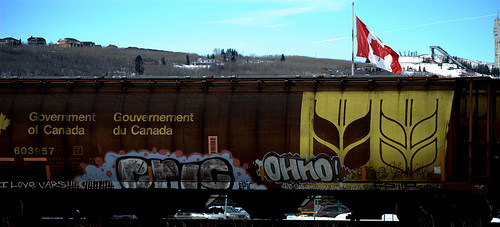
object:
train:
[0, 75, 499, 227]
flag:
[355, 16, 402, 75]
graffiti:
[254, 151, 349, 185]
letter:
[113, 112, 122, 123]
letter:
[130, 125, 139, 136]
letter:
[91, 112, 97, 123]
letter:
[166, 127, 174, 136]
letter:
[27, 126, 35, 135]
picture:
[299, 89, 453, 190]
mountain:
[0, 44, 499, 78]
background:
[1, 1, 500, 223]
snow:
[398, 56, 473, 78]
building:
[1, 37, 22, 48]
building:
[191, 57, 216, 66]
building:
[56, 37, 102, 48]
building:
[27, 36, 47, 45]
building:
[492, 18, 500, 69]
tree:
[133, 54, 145, 75]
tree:
[185, 54, 191, 66]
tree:
[280, 53, 286, 61]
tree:
[161, 56, 167, 65]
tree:
[231, 53, 237, 62]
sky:
[1, 0, 498, 59]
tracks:
[42, 218, 500, 226]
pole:
[350, 1, 354, 76]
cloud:
[224, 0, 340, 27]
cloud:
[422, 12, 500, 26]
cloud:
[311, 38, 349, 46]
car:
[314, 204, 354, 218]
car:
[225, 212, 251, 220]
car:
[192, 212, 227, 220]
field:
[0, 44, 393, 78]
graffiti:
[71, 147, 268, 191]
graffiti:
[0, 180, 114, 189]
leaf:
[369, 38, 392, 61]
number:
[48, 146, 55, 155]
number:
[41, 146, 48, 156]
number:
[27, 146, 34, 155]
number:
[20, 147, 26, 155]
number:
[13, 146, 20, 155]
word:
[113, 111, 195, 123]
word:
[111, 126, 127, 136]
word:
[131, 124, 174, 136]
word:
[27, 125, 40, 136]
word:
[43, 124, 85, 136]